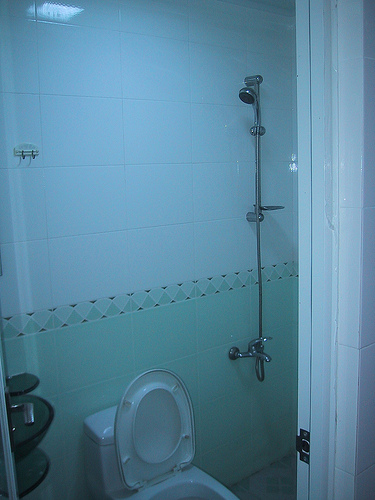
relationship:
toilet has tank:
[71, 369, 249, 494] [79, 362, 152, 487]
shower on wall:
[214, 51, 299, 394] [5, 3, 373, 411]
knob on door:
[6, 386, 40, 445] [0, 155, 27, 500]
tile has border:
[10, 39, 317, 342] [7, 252, 314, 328]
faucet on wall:
[221, 318, 303, 404] [5, 3, 373, 411]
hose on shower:
[247, 114, 282, 337] [214, 51, 299, 394]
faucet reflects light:
[221, 318, 303, 404] [248, 333, 269, 349]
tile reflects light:
[10, 39, 317, 342] [16, 0, 94, 45]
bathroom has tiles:
[1, 3, 368, 489] [12, 7, 297, 385]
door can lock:
[0, 155, 27, 500] [0, 217, 25, 492]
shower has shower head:
[214, 51, 299, 394] [221, 67, 276, 131]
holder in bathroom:
[10, 367, 68, 494] [1, 3, 368, 489]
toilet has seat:
[71, 369, 249, 494] [101, 343, 242, 477]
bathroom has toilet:
[1, 3, 368, 489] [71, 369, 249, 494]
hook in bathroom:
[5, 103, 52, 189] [1, 3, 368, 489]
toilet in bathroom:
[71, 369, 249, 494] [1, 3, 368, 489]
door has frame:
[0, 155, 27, 500] [300, 1, 344, 491]